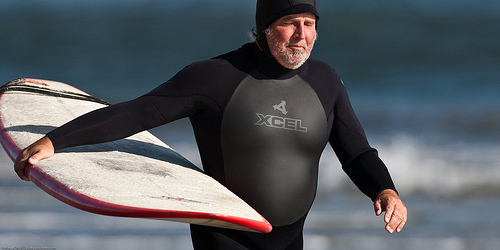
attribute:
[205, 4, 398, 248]
man — standing, white, old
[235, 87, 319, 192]
suit — black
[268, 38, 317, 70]
beard — grey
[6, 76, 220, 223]
surfboard — white, red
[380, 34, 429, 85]
sea — close